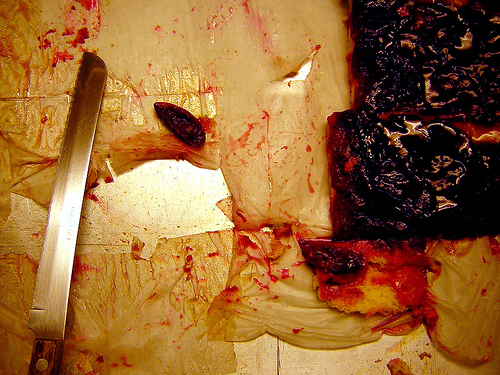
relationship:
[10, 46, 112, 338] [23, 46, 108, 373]
blade of knife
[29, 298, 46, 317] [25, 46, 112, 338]
notch on blade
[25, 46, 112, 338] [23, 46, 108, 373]
blade attached to knife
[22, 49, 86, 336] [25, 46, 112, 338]
edge lining blade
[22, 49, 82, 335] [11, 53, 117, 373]
edge attached to knife